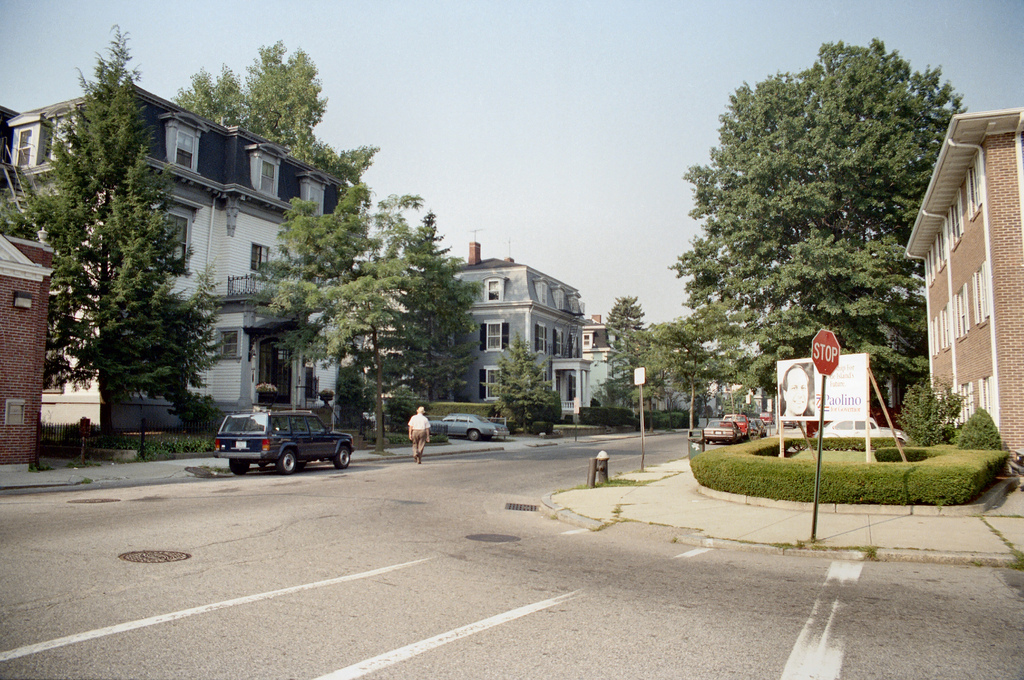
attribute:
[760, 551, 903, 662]
lines — white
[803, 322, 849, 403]
stop sign — red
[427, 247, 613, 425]
house — grey, big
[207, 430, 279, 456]
lights — rear, red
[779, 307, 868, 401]
sign — red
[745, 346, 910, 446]
sign — white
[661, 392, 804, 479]
cars — parked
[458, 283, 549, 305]
window — clear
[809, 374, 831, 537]
pole — metal, dark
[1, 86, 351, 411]
house — large, white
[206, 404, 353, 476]
jeep — blue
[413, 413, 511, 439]
car — blue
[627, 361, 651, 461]
street sign — white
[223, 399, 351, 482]
jeep — blue 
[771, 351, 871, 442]
billboard — White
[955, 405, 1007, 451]
bush — Green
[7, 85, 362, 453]
house — tall, white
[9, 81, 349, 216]
upper level — black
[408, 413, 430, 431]
shirt — white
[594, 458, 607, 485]
hydrant — black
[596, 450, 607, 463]
top — grey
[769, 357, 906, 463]
sign — White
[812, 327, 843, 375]
stop sign — White, red